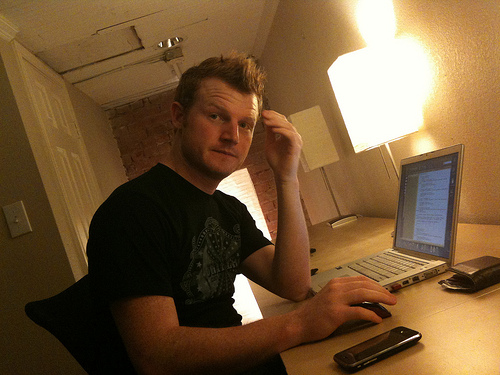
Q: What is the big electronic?
A: Laptop.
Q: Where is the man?
A: At the table.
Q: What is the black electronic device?
A: Phone.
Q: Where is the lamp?
A: Behind the laptop.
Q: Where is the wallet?
A: Next to the laptop.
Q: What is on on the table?
A: Laptop.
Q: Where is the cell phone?
A: On the table.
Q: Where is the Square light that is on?
A: On the wall.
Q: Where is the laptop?
A: On desk.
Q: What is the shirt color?
A: Black.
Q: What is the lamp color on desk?
A: White.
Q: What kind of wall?
A: Brick.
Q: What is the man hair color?
A: Black.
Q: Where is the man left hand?
A: Touching hair.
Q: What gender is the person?
A: Male.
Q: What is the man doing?
A: Working on laptop.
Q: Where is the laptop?
A: On the table.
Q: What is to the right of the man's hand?
A: Phone.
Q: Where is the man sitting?
A: In a chair.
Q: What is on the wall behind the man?
A: A light switch.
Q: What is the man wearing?
A: Black shirt.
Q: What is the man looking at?
A: The camera.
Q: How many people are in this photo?
A: One.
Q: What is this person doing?
A: Using a laptop.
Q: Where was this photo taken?
A: Inside a room.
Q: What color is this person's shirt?
A: Black.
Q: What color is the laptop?
A: Silver.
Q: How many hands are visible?
A: Two.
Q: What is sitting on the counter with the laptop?
A: A wallet and a cellphone.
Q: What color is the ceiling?
A: White.